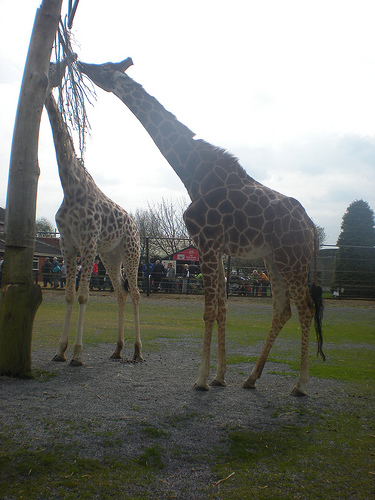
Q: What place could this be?
A: It is a pen.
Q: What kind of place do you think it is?
A: It is a pen.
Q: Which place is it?
A: It is a pen.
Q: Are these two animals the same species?
A: Yes, all the animals are giraffes.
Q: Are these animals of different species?
A: No, all the animals are giraffes.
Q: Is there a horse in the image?
A: No, there are no horses.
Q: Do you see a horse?
A: No, there are no horses.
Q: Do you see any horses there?
A: No, there are no horses.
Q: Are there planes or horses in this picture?
A: No, there are no horses or planes.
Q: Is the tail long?
A: Yes, the tail is long.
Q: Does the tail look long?
A: Yes, the tail is long.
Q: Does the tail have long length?
A: Yes, the tail is long.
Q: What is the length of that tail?
A: The tail is long.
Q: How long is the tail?
A: The tail is long.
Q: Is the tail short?
A: No, the tail is long.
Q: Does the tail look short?
A: No, the tail is long.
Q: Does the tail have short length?
A: No, the tail is long.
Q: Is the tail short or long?
A: The tail is long.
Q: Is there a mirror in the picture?
A: No, there are no mirrors.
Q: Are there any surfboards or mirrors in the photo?
A: No, there are no mirrors or surfboards.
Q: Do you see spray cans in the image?
A: No, there are no spray cans.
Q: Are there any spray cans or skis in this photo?
A: No, there are no spray cans or skis.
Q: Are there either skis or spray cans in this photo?
A: No, there are no spray cans or skis.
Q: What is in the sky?
A: The clouds are in the sky.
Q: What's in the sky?
A: The clouds are in the sky.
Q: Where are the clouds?
A: The clouds are in the sky.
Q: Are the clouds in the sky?
A: Yes, the clouds are in the sky.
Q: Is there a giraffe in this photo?
A: Yes, there is a giraffe.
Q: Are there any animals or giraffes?
A: Yes, there is a giraffe.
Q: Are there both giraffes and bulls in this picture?
A: No, there is a giraffe but no bulls.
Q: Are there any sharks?
A: No, there are no sharks.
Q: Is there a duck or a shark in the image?
A: No, there are no sharks or ducks.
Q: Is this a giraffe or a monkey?
A: This is a giraffe.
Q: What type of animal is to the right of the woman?
A: The animal is a giraffe.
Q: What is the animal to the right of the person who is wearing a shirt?
A: The animal is a giraffe.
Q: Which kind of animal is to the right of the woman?
A: The animal is a giraffe.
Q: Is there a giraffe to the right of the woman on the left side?
A: Yes, there is a giraffe to the right of the woman.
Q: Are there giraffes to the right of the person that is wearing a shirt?
A: Yes, there is a giraffe to the right of the woman.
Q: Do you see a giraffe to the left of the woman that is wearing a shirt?
A: No, the giraffe is to the right of the woman.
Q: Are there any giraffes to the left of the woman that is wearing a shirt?
A: No, the giraffe is to the right of the woman.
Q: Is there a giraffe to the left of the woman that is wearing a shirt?
A: No, the giraffe is to the right of the woman.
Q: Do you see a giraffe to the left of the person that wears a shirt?
A: No, the giraffe is to the right of the woman.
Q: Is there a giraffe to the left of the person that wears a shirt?
A: No, the giraffe is to the right of the woman.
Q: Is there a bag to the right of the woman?
A: No, there is a giraffe to the right of the woman.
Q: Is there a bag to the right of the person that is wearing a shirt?
A: No, there is a giraffe to the right of the woman.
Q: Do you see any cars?
A: No, there are no cars.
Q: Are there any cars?
A: No, there are no cars.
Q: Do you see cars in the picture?
A: No, there are no cars.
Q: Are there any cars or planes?
A: No, there are no cars or planes.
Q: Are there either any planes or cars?
A: No, there are no cars or planes.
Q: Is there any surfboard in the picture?
A: No, there are no surfboards.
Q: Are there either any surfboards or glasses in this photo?
A: No, there are no surfboards or glasses.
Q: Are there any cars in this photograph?
A: No, there are no cars.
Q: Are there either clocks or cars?
A: No, there are no cars or clocks.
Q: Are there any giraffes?
A: Yes, there is a giraffe.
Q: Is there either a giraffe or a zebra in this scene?
A: Yes, there is a giraffe.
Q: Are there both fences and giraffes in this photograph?
A: Yes, there are both a giraffe and a fence.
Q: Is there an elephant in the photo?
A: No, there are no elephants.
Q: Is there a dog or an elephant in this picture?
A: No, there are no elephants or dogs.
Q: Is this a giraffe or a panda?
A: This is a giraffe.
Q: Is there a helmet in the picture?
A: No, there are no helmets.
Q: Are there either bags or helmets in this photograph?
A: No, there are no helmets or bags.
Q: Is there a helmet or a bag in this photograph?
A: No, there are no helmets or bags.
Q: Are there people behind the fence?
A: Yes, there is a person behind the fence.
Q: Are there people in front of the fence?
A: No, the person is behind the fence.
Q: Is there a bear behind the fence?
A: No, there is a person behind the fence.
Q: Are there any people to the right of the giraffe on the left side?
A: Yes, there is a person to the right of the giraffe.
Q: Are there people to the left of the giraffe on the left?
A: No, the person is to the right of the giraffe.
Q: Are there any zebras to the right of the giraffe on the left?
A: No, there is a person to the right of the giraffe.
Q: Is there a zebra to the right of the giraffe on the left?
A: No, there is a person to the right of the giraffe.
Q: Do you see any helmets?
A: No, there are no helmets.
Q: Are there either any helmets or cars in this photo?
A: No, there are no helmets or cars.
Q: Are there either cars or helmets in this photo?
A: No, there are no helmets or cars.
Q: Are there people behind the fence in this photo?
A: Yes, there is a person behind the fence.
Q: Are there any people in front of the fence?
A: No, the person is behind the fence.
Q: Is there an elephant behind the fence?
A: No, there is a person behind the fence.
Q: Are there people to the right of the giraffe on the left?
A: Yes, there is a person to the right of the giraffe.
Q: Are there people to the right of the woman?
A: Yes, there is a person to the right of the woman.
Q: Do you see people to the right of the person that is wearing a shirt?
A: Yes, there is a person to the right of the woman.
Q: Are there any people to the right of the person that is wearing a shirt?
A: Yes, there is a person to the right of the woman.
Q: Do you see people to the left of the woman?
A: No, the person is to the right of the woman.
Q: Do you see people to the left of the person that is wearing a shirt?
A: No, the person is to the right of the woman.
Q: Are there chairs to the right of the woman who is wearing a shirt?
A: No, there is a person to the right of the woman.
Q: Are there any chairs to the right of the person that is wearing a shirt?
A: No, there is a person to the right of the woman.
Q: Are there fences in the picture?
A: Yes, there is a fence.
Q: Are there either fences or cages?
A: Yes, there is a fence.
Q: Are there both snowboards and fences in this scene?
A: No, there is a fence but no snowboards.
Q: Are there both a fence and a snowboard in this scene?
A: No, there is a fence but no snowboards.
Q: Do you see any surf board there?
A: No, there are no surfboards.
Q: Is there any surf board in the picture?
A: No, there are no surfboards.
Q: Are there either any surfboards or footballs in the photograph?
A: No, there are no surfboards or footballs.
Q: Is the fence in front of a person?
A: Yes, the fence is in front of a person.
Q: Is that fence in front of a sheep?
A: No, the fence is in front of a person.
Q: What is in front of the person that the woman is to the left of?
A: The fence is in front of the person.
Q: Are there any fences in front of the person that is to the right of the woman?
A: Yes, there is a fence in front of the person.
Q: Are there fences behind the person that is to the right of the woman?
A: No, the fence is in front of the person.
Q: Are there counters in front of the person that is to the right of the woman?
A: No, there is a fence in front of the person.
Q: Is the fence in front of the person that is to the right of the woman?
A: Yes, the fence is in front of the person.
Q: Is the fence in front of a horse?
A: No, the fence is in front of the person.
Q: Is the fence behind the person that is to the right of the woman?
A: No, the fence is in front of the person.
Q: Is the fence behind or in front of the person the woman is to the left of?
A: The fence is in front of the person.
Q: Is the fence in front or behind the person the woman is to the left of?
A: The fence is in front of the person.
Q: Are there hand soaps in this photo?
A: No, there are no hand soaps.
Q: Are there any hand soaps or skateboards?
A: No, there are no hand soaps or skateboards.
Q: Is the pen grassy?
A: Yes, the pen is grassy.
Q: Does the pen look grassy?
A: Yes, the pen is grassy.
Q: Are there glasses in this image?
A: No, there are no glasses.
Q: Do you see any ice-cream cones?
A: No, there are no ice-cream cones.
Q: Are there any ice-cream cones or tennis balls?
A: No, there are no ice-cream cones or tennis balls.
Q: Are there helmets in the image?
A: No, there are no helmets.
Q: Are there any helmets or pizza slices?
A: No, there are no helmets or pizza slices.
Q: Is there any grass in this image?
A: Yes, there is grass.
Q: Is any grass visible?
A: Yes, there is grass.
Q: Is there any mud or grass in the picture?
A: Yes, there is grass.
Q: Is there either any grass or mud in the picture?
A: Yes, there is grass.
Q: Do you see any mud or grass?
A: Yes, there is grass.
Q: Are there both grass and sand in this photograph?
A: No, there is grass but no sand.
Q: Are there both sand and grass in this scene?
A: No, there is grass but no sand.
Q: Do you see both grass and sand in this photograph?
A: No, there is grass but no sand.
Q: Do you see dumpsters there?
A: No, there are no dumpsters.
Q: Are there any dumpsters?
A: No, there are no dumpsters.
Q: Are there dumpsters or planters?
A: No, there are no dumpsters or planters.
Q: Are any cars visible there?
A: No, there are no cars.